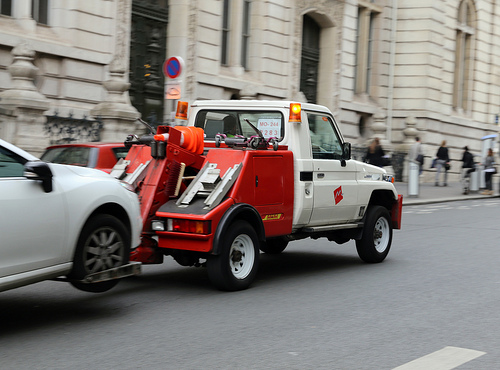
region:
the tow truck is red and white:
[139, 115, 389, 236]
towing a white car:
[12, 157, 150, 292]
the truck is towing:
[77, 100, 208, 275]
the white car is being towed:
[0, 123, 252, 286]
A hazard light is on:
[291, 98, 302, 121]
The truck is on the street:
[4, 91, 433, 368]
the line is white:
[430, 331, 467, 368]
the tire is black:
[219, 205, 265, 287]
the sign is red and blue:
[162, 56, 182, 76]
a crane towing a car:
[0, 2, 486, 362]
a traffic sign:
[164, 55, 182, 80]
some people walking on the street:
[370, 128, 495, 191]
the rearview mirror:
[22, 162, 52, 193]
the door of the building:
[298, 5, 329, 105]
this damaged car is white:
[0, 143, 141, 302]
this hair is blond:
[368, 138, 382, 153]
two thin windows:
[219, 0, 256, 73]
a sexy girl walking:
[433, 140, 452, 186]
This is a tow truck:
[95, 93, 440, 280]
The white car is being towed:
[3, 118, 219, 293]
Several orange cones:
[147, 114, 212, 154]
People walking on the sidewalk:
[368, 126, 488, 191]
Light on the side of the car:
[282, 95, 307, 127]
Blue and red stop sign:
[151, 45, 189, 85]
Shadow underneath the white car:
[15, 288, 145, 327]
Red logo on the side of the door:
[328, 179, 346, 207]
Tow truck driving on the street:
[201, 215, 421, 318]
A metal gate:
[44, 105, 104, 140]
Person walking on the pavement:
[448, 136, 478, 198]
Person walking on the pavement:
[428, 133, 450, 192]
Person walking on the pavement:
[358, 128, 385, 176]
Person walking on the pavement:
[476, 143, 498, 180]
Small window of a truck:
[300, 108, 347, 170]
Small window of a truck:
[193, 101, 300, 158]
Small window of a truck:
[199, 108, 249, 140]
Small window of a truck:
[3, 147, 29, 189]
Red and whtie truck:
[90, 61, 455, 282]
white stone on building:
[259, 41, 295, 62]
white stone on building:
[262, 59, 280, 84]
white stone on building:
[344, 65, 361, 80]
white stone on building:
[337, 84, 360, 97]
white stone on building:
[337, 33, 354, 54]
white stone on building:
[336, 112, 359, 124]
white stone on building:
[395, 67, 434, 88]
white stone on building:
[427, 62, 442, 74]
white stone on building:
[408, 30, 442, 49]